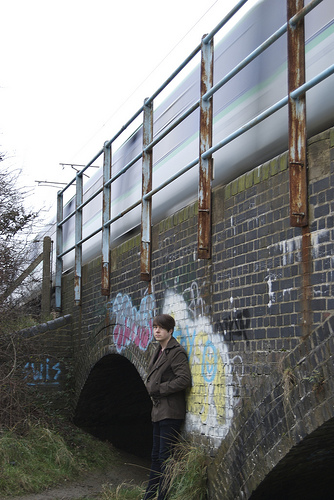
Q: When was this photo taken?
A: In the daytime.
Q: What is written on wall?
A: Graffiti.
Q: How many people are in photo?
A: One.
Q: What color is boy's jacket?
A: Brown.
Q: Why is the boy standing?
A: Posing for photo.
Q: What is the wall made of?
A: Bricks.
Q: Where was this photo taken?
A: By a tunnel.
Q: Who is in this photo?
A: A boy.